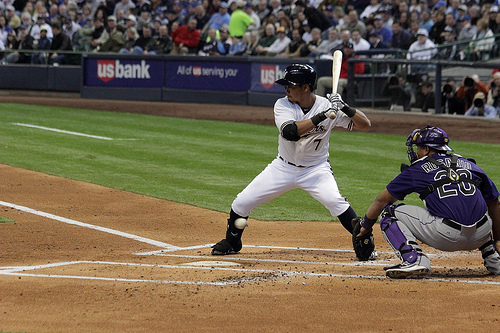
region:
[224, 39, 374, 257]
A batter hitting at ball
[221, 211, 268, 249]
A blurry baseball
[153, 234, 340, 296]
Dark dirt or gravel on home plate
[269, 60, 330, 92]
A shiney black helmet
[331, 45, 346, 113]
A light colored bat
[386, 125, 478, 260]
An umpire squatting behind batter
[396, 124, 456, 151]
Umpire wearing a blue catcher mask and helmet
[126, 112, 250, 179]
A field of green grass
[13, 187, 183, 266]
A white chalk line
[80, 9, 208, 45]
A large crowd in stands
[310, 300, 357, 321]
dirt on the ground.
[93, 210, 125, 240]
chalk on the baseline.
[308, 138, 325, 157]
number on the jersey.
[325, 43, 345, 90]
bat in player's hands.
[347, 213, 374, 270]
glove on catcher's hand.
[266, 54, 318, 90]
helmet on batter's head.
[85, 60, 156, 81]
advertisement on the wall.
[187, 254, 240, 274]
home plate in batter's box.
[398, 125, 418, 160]
mask on catcher's face.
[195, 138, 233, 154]
grass in foul territory.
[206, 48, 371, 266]
Baseball player holding baseball bat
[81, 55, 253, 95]
Advertisement banner for a company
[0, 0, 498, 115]
Crowd watching the baseball game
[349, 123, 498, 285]
Umpire crouching behind the batter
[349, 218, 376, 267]
Baseball glove on man's hand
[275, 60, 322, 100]
Helmet on baseball player's head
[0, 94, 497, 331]
Baseball field with white lines and grass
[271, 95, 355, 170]
Baseball player's team jersey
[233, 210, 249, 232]
Baseball in mid flight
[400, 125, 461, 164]
Umpire's helmet with face protection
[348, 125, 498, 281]
baseball catcher ready for a pitch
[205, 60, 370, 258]
At bat batter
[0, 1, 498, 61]
crowd eagerly watches ball game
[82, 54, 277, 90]
US bank ad at a baseball game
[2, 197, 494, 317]
Ball crossing over home plate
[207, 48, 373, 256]
batter showing perfect at bat position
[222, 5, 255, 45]
person wearing a neon green shirt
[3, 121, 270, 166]
well manicure lawn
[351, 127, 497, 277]
baseball player wearing a purple uniform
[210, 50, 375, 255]
baseball player wearing a white uniform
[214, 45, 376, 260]
baseball player about to hit a ball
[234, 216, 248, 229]
a white ball flying in the air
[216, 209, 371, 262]
baseball player wearing black boots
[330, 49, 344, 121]
a wooden baseball bat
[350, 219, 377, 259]
a catcher holding a black mitt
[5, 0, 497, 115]
spectators in the bleachers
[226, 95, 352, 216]
man wearing a white uniform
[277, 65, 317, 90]
man wearing a black hard hat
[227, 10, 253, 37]
man wearing a green lime shirt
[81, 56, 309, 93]
advertisement panels in baseball stadium